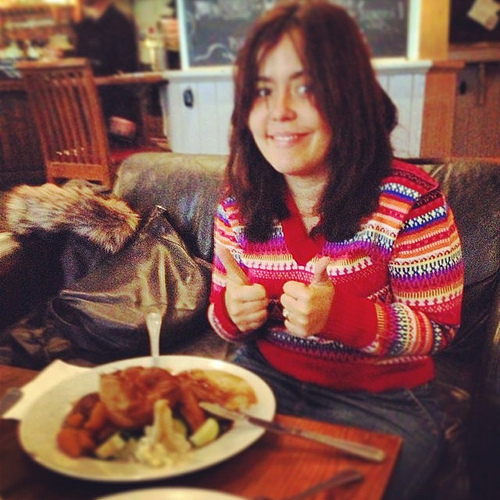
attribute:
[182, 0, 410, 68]
chalk board — black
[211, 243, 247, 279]
thumb — up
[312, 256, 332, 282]
thumb — up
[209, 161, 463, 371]
sweater — multicolored , red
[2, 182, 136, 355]
jacket — black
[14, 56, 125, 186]
chair — wooden, brown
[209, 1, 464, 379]
woman — happy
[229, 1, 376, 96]
hair — brown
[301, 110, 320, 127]
skin — light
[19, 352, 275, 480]
plate — white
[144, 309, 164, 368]
spoon — metallic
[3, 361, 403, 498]
table — wooden